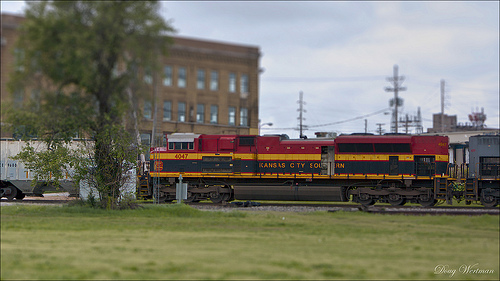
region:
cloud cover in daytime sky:
[154, 2, 498, 130]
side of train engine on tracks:
[151, 132, 451, 209]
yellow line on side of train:
[150, 134, 447, 177]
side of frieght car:
[0, 138, 114, 196]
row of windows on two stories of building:
[132, 64, 252, 126]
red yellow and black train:
[162, 124, 447, 194]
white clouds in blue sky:
[195, 8, 217, 26]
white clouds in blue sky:
[243, 5, 263, 29]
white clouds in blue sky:
[273, 8, 303, 46]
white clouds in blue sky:
[305, 22, 351, 69]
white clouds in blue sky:
[379, 23, 418, 69]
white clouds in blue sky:
[444, 16, 497, 51]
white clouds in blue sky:
[422, 21, 457, 48]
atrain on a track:
[145, 122, 403, 232]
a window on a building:
[196, 65, 202, 85]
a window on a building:
[210, 68, 220, 91]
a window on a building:
[221, 60, 244, 95]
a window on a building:
[237, 75, 247, 104]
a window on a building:
[240, 110, 247, 127]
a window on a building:
[233, 106, 235, 119]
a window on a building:
[194, 99, 206, 122]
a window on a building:
[179, 95, 186, 127]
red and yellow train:
[128, 129, 460, 209]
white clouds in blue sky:
[260, 11, 304, 51]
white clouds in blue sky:
[274, 55, 304, 92]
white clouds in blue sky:
[322, 22, 353, 56]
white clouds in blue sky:
[351, 58, 372, 96]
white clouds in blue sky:
[360, 11, 388, 45]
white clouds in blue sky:
[402, 12, 434, 50]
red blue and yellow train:
[174, 119, 481, 226]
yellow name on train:
[218, 139, 350, 189]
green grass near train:
[158, 223, 323, 265]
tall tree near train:
[52, 12, 148, 177]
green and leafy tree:
[40, 9, 149, 181]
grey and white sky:
[290, 16, 395, 112]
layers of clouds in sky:
[280, 16, 387, 108]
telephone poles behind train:
[365, 63, 441, 143]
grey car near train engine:
[1, 136, 107, 188]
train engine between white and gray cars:
[6, 126, 496, 210]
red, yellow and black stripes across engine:
[149, 130, 452, 197]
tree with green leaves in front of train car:
[18, 3, 161, 205]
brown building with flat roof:
[3, 11, 263, 146]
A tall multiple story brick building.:
[0, 10, 263, 133]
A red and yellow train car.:
[147, 126, 457, 206]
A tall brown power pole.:
[379, 62, 407, 132]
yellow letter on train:
[255, 159, 265, 171]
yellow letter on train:
[261, 160, 271, 170]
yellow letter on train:
[266, 159, 274, 169]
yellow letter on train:
[270, 159, 277, 170]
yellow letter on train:
[274, 160, 283, 168]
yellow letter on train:
[278, 160, 289, 169]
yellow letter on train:
[286, 159, 296, 169]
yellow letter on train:
[293, 160, 303, 168]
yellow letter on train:
[297, 160, 304, 167]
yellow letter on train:
[307, 161, 314, 169]